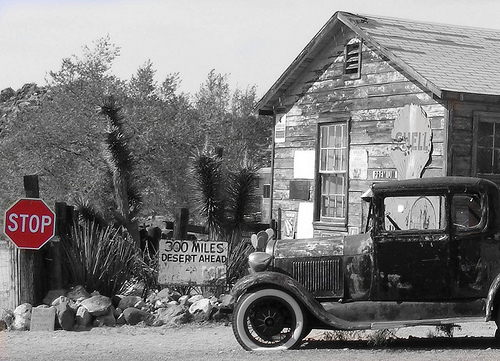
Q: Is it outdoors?
A: Yes, it is outdoors.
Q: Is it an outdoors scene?
A: Yes, it is outdoors.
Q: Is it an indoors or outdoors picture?
A: It is outdoors.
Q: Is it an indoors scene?
A: No, it is outdoors.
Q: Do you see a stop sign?
A: Yes, there is a stop sign.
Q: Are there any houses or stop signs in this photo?
A: Yes, there is a stop sign.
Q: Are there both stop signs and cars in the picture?
A: Yes, there are both a stop sign and a car.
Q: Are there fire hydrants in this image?
A: No, there are no fire hydrants.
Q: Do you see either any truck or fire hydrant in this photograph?
A: No, there are no fire hydrants or trucks.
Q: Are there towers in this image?
A: No, there are no towers.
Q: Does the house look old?
A: Yes, the house is old.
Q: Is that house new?
A: No, the house is old.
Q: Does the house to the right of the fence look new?
A: No, the house is old.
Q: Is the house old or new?
A: The house is old.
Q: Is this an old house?
A: Yes, this is an old house.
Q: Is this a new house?
A: No, this is an old house.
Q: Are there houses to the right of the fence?
A: Yes, there is a house to the right of the fence.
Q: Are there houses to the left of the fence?
A: No, the house is to the right of the fence.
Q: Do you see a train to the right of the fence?
A: No, there is a house to the right of the fence.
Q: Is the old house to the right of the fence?
A: Yes, the house is to the right of the fence.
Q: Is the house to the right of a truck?
A: No, the house is to the right of the fence.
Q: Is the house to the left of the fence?
A: No, the house is to the right of the fence.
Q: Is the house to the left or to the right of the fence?
A: The house is to the right of the fence.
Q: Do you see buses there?
A: No, there are no buses.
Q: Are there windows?
A: Yes, there is a window.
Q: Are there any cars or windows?
A: Yes, there is a window.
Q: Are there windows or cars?
A: Yes, there is a window.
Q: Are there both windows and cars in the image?
A: Yes, there are both a window and a car.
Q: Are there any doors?
A: No, there are no doors.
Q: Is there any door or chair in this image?
A: No, there are no doors or chairs.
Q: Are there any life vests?
A: No, there are no life vests.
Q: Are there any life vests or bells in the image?
A: No, there are no life vests or bells.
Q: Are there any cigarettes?
A: No, there are no cigarettes.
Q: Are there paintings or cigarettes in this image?
A: No, there are no cigarettes or paintings.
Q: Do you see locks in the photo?
A: No, there are no locks.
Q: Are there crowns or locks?
A: No, there are no locks or crowns.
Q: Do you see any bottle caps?
A: No, there are no bottle caps.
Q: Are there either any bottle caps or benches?
A: No, there are no bottle caps or benches.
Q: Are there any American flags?
A: No, there are no American flags.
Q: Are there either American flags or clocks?
A: No, there are no American flags or clocks.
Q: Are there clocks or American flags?
A: No, there are no American flags or clocks.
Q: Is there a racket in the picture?
A: No, there are no rackets.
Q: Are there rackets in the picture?
A: No, there are no rackets.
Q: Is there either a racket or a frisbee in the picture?
A: No, there are no rackets or frisbees.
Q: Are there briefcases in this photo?
A: No, there are no briefcases.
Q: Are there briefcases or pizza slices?
A: No, there are no briefcases or pizza slices.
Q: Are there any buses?
A: No, there are no buses.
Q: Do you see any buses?
A: No, there are no buses.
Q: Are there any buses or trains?
A: No, there are no buses or trains.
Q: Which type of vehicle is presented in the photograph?
A: The vehicle is a car.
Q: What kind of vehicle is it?
A: The vehicle is a car.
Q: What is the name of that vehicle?
A: This is a car.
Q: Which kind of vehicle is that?
A: This is a car.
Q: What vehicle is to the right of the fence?
A: The vehicle is a car.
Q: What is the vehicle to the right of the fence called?
A: The vehicle is a car.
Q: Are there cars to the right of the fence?
A: Yes, there is a car to the right of the fence.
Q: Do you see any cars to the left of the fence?
A: No, the car is to the right of the fence.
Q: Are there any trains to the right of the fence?
A: No, there is a car to the right of the fence.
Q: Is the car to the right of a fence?
A: Yes, the car is to the right of a fence.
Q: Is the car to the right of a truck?
A: No, the car is to the right of a fence.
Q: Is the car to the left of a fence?
A: No, the car is to the right of a fence.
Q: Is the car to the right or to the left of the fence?
A: The car is to the right of the fence.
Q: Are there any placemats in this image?
A: No, there are no placemats.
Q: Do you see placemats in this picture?
A: No, there are no placemats.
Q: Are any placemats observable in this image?
A: No, there are no placemats.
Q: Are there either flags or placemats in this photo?
A: No, there are no placemats or flags.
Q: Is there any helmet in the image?
A: No, there are no helmets.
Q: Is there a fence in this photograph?
A: Yes, there is a fence.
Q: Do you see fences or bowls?
A: Yes, there is a fence.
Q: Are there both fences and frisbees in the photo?
A: No, there is a fence but no frisbees.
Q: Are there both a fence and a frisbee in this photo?
A: No, there is a fence but no frisbees.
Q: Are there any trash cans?
A: No, there are no trash cans.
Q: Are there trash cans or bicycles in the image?
A: No, there are no trash cans or bicycles.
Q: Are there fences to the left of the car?
A: Yes, there is a fence to the left of the car.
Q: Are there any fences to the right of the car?
A: No, the fence is to the left of the car.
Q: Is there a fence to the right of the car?
A: No, the fence is to the left of the car.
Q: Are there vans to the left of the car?
A: No, there is a fence to the left of the car.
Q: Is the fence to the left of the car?
A: Yes, the fence is to the left of the car.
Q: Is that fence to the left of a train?
A: No, the fence is to the left of the car.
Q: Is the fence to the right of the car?
A: No, the fence is to the left of the car.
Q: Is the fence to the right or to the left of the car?
A: The fence is to the left of the car.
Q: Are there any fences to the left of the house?
A: Yes, there is a fence to the left of the house.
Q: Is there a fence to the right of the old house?
A: No, the fence is to the left of the house.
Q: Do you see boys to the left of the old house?
A: No, there is a fence to the left of the house.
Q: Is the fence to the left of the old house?
A: Yes, the fence is to the left of the house.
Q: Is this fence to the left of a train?
A: No, the fence is to the left of the house.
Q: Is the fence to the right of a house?
A: No, the fence is to the left of a house.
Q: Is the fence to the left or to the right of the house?
A: The fence is to the left of the house.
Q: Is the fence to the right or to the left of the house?
A: The fence is to the left of the house.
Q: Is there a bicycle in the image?
A: No, there are no bicycles.